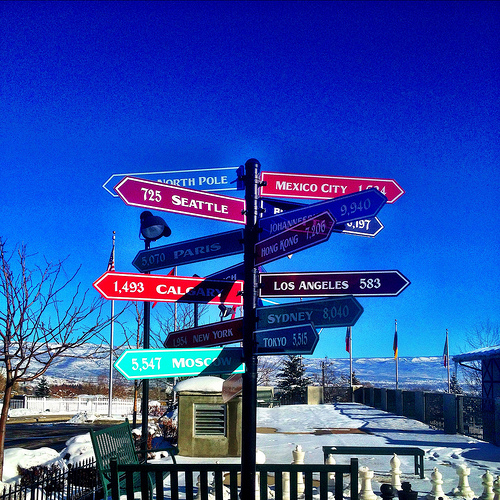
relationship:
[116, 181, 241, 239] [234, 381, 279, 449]
sign on pole